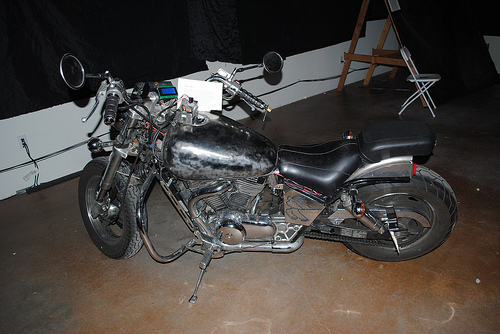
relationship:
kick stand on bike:
[189, 248, 213, 303] [59, 53, 458, 304]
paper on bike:
[177, 78, 224, 111] [59, 53, 458, 304]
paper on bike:
[175, 77, 223, 115] [59, 53, 458, 304]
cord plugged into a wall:
[23, 140, 48, 187] [0, 0, 401, 199]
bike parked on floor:
[59, 53, 458, 304] [0, 68, 485, 329]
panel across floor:
[3, 36, 388, 201] [14, 189, 63, 328]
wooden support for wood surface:
[334, 10, 429, 90] [383, 0, 485, 105]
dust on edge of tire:
[93, 154, 144, 259] [76, 157, 148, 260]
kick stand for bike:
[189, 248, 213, 303] [59, 53, 458, 304]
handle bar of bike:
[105, 86, 120, 131] [59, 53, 458, 304]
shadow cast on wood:
[237, 72, 287, 85] [2, 30, 384, 200]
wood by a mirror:
[2, 30, 384, 200] [232, 52, 284, 72]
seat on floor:
[390, 45, 445, 120] [8, 42, 497, 332]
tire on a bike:
[78, 156, 149, 259] [24, 47, 499, 329]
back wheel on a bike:
[329, 164, 459, 262] [24, 47, 499, 329]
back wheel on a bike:
[341, 158, 460, 265] [48, 47, 461, 277]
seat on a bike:
[273, 117, 366, 197] [38, 26, 466, 274]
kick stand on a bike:
[187, 237, 224, 306] [33, 42, 479, 315]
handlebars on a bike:
[58, 50, 281, 124] [57, 41, 465, 307]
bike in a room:
[57, 41, 465, 307] [2, 1, 485, 332]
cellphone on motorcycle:
[157, 85, 178, 99] [46, 40, 470, 275]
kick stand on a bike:
[189, 248, 213, 303] [59, 53, 458, 304]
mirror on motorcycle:
[265, 53, 282, 72] [22, 34, 467, 307]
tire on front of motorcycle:
[78, 156, 149, 259] [46, 40, 470, 275]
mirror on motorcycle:
[63, 56, 84, 86] [69, 67, 491, 299]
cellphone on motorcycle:
[146, 76, 182, 103] [85, 92, 370, 247]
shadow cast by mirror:
[72, 94, 90, 104] [57, 52, 109, 95]